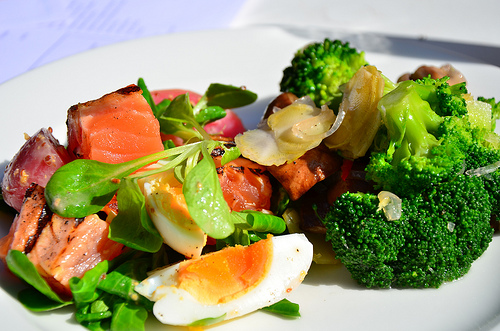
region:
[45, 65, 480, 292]
a plate ful of food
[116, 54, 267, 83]
platre is white in color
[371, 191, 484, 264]
vegetable are green in color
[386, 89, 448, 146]
vegetable stalks are bright green in color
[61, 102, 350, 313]
the food is colorfull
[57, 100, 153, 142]
red pieces on the plate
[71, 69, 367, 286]
food is apetising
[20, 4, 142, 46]
the floor is bright white in color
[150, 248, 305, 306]
the white part is delicious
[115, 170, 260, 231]
the green parts is apetising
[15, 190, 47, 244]
a piece of carrot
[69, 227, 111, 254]
a piece of carrot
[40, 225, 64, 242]
a piece of carrot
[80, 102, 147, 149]
a piece of carrot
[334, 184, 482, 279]
a piece of cauliflower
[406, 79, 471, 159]
a piece of cauliflower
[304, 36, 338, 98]
a piece of cauliflower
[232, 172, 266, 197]
a piece of tomatoe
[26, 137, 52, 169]
a piece of tomatoe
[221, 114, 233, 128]
a piece of tomatoe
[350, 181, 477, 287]
the broccoli is green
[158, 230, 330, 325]
the egg is half cut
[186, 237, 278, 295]
the york is orange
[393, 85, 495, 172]
brocollis is uncooked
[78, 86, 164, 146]
the meat is uncooked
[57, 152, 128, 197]
the leaves are green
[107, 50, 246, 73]
the plate is white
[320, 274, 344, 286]
shadow is on the plate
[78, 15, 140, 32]
the surface is white